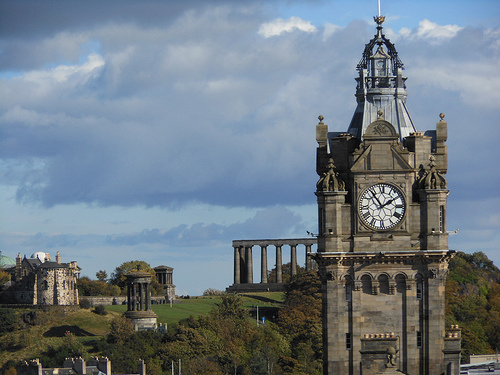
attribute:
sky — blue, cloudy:
[1, 0, 498, 299]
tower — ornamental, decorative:
[315, 2, 445, 375]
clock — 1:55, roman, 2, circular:
[358, 182, 408, 233]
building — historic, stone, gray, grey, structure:
[225, 241, 317, 292]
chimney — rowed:
[170, 361, 175, 375]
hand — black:
[369, 188, 382, 207]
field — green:
[104, 293, 285, 321]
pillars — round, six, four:
[126, 271, 155, 319]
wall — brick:
[84, 295, 166, 302]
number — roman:
[378, 185, 386, 193]